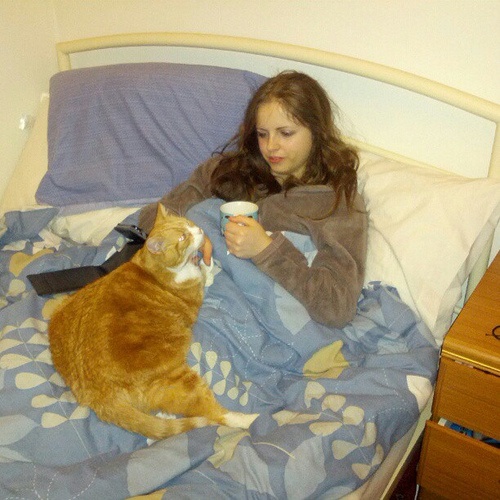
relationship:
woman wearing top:
[135, 67, 368, 330] [132, 143, 372, 332]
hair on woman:
[205, 65, 360, 221] [135, 67, 368, 330]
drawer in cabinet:
[414, 412, 497, 497] [414, 249, 500, 499]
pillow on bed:
[33, 58, 270, 211] [25, 21, 490, 383]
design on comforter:
[271, 407, 320, 430] [2, 200, 442, 497]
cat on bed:
[41, 208, 280, 447] [19, 37, 425, 487]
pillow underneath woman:
[355, 150, 497, 345] [135, 67, 368, 330]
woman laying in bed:
[120, 77, 411, 334] [8, 88, 497, 493]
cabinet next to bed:
[415, 250, 497, 498] [4, 30, 499, 498]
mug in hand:
[211, 190, 278, 255] [219, 210, 271, 259]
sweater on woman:
[137, 150, 370, 328] [159, 73, 389, 313]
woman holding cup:
[135, 67, 368, 330] [217, 191, 265, 265]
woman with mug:
[135, 67, 368, 330] [217, 197, 261, 238]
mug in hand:
[217, 197, 261, 238] [212, 216, 271, 251]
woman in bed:
[135, 67, 368, 330] [4, 30, 499, 498]